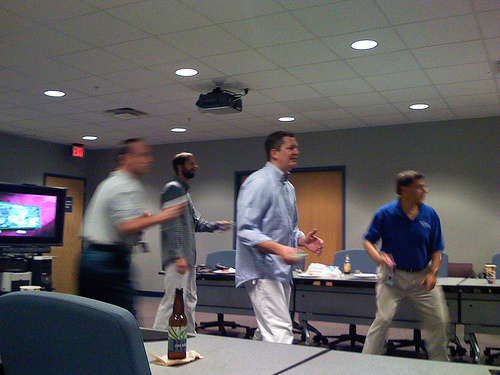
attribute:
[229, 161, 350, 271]
door — wooden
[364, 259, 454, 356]
pants — white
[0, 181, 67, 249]
television — black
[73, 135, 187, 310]
man — playing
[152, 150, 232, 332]
man — playing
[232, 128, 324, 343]
man — playing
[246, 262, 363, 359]
pant — white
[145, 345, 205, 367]
napkin — beige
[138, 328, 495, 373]
table — grey, hard, gray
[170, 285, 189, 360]
bottle — brown, beet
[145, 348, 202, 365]
napking — brown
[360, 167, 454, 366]
man — playing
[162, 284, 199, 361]
bottle — brown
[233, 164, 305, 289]
button down — blue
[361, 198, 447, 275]
shirt — bright blue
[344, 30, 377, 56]
light — round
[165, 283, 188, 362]
bottle — brown